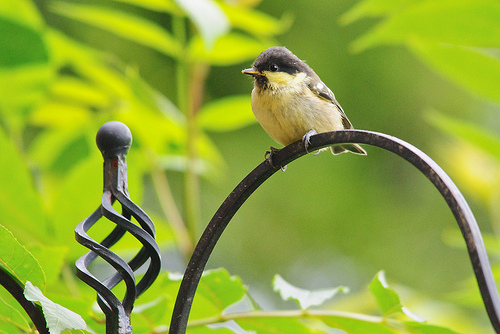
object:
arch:
[166, 126, 499, 334]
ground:
[0, 234, 500, 334]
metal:
[169, 128, 498, 334]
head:
[241, 46, 303, 82]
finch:
[241, 47, 312, 130]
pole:
[74, 122, 161, 334]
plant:
[0, 0, 294, 270]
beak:
[241, 65, 265, 78]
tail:
[325, 142, 367, 157]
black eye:
[270, 64, 280, 71]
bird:
[240, 47, 368, 173]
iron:
[0, 121, 161, 334]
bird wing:
[304, 77, 357, 130]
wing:
[302, 73, 354, 129]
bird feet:
[300, 130, 316, 157]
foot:
[262, 145, 287, 172]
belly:
[250, 83, 315, 144]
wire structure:
[165, 126, 500, 334]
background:
[0, 0, 500, 334]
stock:
[172, 19, 208, 245]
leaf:
[0, 0, 500, 334]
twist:
[72, 185, 162, 315]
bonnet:
[254, 47, 304, 64]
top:
[93, 120, 133, 156]